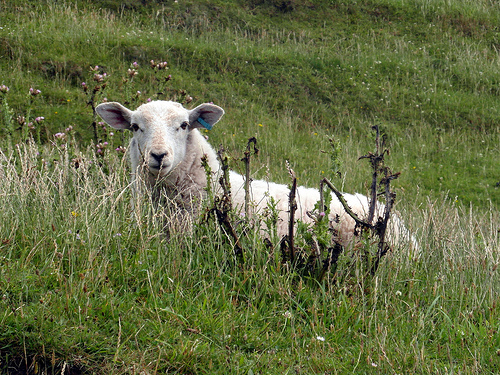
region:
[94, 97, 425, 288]
Sheep laying in the grass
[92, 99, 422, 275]
White sheep laying in the grass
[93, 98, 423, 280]
Sheep in the grass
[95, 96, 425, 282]
White sheep in the grass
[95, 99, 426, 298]
Sheep laying in tall grass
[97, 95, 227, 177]
Head of a sheep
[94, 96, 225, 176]
Head of a white sheep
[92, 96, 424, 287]
Sheep with a blue ear tag laying down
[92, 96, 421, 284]
White sheep with a blue ear tag laying in grass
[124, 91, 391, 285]
sheep is in grass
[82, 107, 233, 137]
sheep has white ears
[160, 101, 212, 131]
blue tag in ear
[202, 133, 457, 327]
long grasses in front of sheep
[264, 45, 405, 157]
long and green grass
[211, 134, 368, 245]
sheep has short fur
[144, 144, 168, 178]
sheep has brown nose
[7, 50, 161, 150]
small buds on plants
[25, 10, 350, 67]
long grass behind sheep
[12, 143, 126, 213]
brown stems on grass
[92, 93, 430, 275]
white sheep in the grass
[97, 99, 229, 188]
blue tag on the sheep ear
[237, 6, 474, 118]
green long grass in the back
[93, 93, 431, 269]
White sheep looking forward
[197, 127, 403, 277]
dark tall weeds in front of sheep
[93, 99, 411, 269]
tan color sheep has dark black eyes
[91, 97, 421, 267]
white and brown sheep standing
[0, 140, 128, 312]
white tall grass in front of sheep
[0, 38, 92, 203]
pink and white flowers in the grass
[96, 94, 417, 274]
White sheep with long white ears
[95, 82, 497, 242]
an adult sheep walking in some grass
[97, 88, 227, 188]
the head of an adult sheep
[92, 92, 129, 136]
the ear of an adult sheep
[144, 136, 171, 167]
the mouth of an adult sheep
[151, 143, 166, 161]
the nose of an adult sheep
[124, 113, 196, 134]
the eyes of an adult sheep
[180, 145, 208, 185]
the wool of an adult sheep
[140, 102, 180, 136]
the forehead of an adult sheep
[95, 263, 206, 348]
a bunch of wild sprouted grass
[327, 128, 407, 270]
twigs that have sprouted from the ground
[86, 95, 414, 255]
sheep in the grass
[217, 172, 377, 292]
plants growing in the grass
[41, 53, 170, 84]
flowers in the grass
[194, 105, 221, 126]
ear of the sheep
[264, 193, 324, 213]
wool of the sheep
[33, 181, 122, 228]
weeds in the ground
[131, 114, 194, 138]
eyes of the sheep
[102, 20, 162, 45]
daisies in the grass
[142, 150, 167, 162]
nose of the sheep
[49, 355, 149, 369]
dirt on the ground